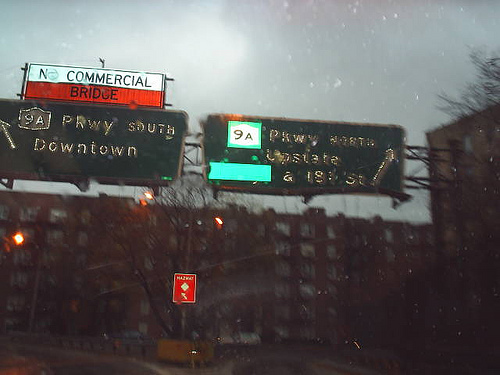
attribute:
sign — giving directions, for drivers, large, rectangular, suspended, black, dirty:
[201, 113, 406, 197]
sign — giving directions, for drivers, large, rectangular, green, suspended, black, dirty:
[0, 98, 188, 189]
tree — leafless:
[116, 177, 274, 336]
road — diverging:
[1, 343, 158, 373]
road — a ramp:
[236, 357, 360, 374]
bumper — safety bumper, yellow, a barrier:
[156, 338, 216, 363]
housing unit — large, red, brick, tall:
[2, 189, 437, 347]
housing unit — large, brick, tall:
[426, 103, 498, 374]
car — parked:
[216, 332, 260, 346]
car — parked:
[105, 328, 153, 340]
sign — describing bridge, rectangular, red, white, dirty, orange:
[21, 62, 167, 110]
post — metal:
[446, 137, 474, 371]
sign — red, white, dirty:
[173, 272, 198, 303]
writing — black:
[39, 66, 153, 100]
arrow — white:
[180, 291, 190, 300]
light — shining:
[14, 234, 26, 244]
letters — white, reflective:
[32, 114, 176, 158]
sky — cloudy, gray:
[0, 2, 497, 223]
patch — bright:
[228, 120, 263, 149]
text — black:
[233, 128, 254, 142]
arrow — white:
[0, 120, 17, 149]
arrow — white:
[371, 146, 397, 183]